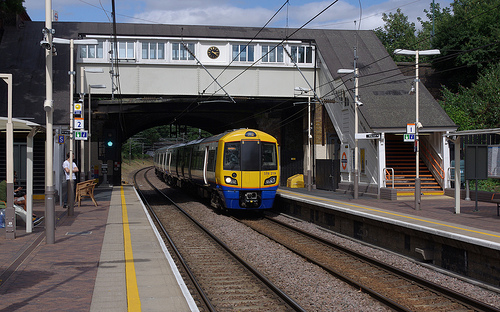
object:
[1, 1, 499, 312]
train is arriving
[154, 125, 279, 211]
train is yellow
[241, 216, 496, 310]
train rail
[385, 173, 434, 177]
stairs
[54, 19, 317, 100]
bridge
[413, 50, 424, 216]
electric pole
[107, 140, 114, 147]
traffic light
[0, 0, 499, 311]
train station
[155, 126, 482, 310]
train on tracks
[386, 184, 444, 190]
orange stairs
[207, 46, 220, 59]
clock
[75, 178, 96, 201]
chairs sitting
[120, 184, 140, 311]
yellow line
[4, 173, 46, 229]
man sitting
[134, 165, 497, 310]
two train tracks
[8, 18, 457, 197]
building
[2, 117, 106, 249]
waiting area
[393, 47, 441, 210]
lights are used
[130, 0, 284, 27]
clouds in the sky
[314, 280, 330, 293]
gravel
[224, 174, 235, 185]
train has a light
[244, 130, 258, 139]
headlight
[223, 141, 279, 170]
windshield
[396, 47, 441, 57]
streetlight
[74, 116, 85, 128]
sign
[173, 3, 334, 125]
power line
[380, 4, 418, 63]
trees with leaves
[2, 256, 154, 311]
shadow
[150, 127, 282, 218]
train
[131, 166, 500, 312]
railroad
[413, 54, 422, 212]
pole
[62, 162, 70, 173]
arms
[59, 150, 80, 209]
man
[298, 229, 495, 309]
tracks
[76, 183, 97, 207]
chairs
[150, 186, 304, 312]
tracks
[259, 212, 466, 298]
metal railing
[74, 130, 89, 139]
sign